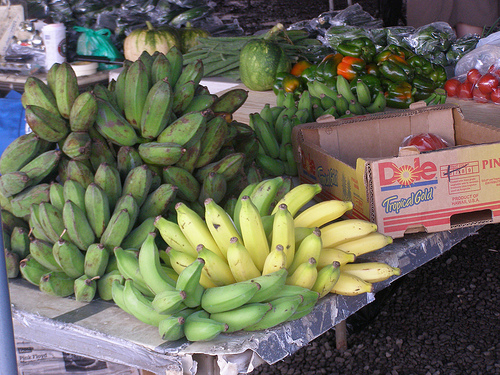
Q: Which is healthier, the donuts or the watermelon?
A: The watermelon is healthier than the donuts.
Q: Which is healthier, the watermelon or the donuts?
A: The watermelon is healthier than the donuts.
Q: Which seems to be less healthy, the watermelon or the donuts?
A: The donuts is less healthy than the watermelon.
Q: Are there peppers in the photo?
A: Yes, there are peppers.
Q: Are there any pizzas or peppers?
A: Yes, there are peppers.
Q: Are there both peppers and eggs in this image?
A: No, there are peppers but no eggs.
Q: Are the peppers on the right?
A: Yes, the peppers are on the right of the image.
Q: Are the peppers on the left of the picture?
A: No, the peppers are on the right of the image.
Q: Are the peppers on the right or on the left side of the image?
A: The peppers are on the right of the image.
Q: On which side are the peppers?
A: The peppers are on the right of the image.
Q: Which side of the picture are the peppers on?
A: The peppers are on the right of the image.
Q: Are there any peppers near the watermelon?
A: Yes, there are peppers near the watermelon.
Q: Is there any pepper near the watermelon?
A: Yes, there are peppers near the watermelon.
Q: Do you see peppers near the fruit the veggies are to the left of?
A: Yes, there are peppers near the watermelon.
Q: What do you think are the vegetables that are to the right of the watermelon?
A: The vegetables are peppers.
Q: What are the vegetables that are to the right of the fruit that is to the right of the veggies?
A: The vegetables are peppers.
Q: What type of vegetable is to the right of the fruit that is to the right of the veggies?
A: The vegetables are peppers.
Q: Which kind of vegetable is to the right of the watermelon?
A: The vegetables are peppers.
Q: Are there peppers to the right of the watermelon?
A: Yes, there are peppers to the right of the watermelon.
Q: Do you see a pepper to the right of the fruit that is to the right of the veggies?
A: Yes, there are peppers to the right of the watermelon.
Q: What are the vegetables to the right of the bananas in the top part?
A: The vegetables are peppers.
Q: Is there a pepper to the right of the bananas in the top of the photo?
A: Yes, there are peppers to the right of the bananas.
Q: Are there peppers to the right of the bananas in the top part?
A: Yes, there are peppers to the right of the bananas.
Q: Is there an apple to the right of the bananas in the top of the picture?
A: No, there are peppers to the right of the bananas.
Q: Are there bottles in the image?
A: No, there are no bottles.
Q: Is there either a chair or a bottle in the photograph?
A: No, there are no bottles or chairs.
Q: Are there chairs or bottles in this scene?
A: No, there are no bottles or chairs.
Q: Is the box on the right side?
A: Yes, the box is on the right of the image.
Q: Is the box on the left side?
A: No, the box is on the right of the image.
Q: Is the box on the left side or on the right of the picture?
A: The box is on the right of the image.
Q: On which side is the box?
A: The box is on the right of the image.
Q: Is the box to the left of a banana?
A: No, the box is to the right of a banana.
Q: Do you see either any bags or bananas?
A: Yes, there are bananas.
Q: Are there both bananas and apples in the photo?
A: No, there are bananas but no apples.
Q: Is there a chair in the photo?
A: No, there are no chairs.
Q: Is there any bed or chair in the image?
A: No, there are no chairs or beds.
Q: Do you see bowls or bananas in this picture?
A: Yes, there are bananas.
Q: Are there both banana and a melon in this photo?
A: No, there are bananas but no melons.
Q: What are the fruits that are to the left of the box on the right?
A: The fruits are bananas.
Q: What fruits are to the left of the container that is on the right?
A: The fruits are bananas.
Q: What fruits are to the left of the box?
A: The fruits are bananas.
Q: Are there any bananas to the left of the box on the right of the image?
A: Yes, there are bananas to the left of the box.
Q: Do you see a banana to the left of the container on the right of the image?
A: Yes, there are bananas to the left of the box.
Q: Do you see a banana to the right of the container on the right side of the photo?
A: No, the bananas are to the left of the box.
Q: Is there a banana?
A: Yes, there are bananas.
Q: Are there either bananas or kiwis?
A: Yes, there are bananas.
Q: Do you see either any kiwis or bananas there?
A: Yes, there are bananas.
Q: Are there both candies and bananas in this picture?
A: No, there are bananas but no candies.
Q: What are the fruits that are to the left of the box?
A: The fruits are bananas.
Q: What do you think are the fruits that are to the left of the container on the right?
A: The fruits are bananas.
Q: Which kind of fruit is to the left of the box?
A: The fruits are bananas.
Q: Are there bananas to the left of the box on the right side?
A: Yes, there are bananas to the left of the box.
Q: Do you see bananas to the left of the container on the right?
A: Yes, there are bananas to the left of the box.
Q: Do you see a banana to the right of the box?
A: No, the bananas are to the left of the box.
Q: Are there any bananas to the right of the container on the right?
A: No, the bananas are to the left of the box.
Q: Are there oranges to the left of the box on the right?
A: No, there are bananas to the left of the box.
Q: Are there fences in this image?
A: No, there are no fences.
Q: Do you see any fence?
A: No, there are no fences.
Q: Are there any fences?
A: No, there are no fences.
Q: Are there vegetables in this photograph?
A: Yes, there are vegetables.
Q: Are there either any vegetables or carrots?
A: Yes, there are vegetables.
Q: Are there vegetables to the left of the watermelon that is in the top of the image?
A: Yes, there are vegetables to the left of the watermelon.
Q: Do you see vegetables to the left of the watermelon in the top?
A: Yes, there are vegetables to the left of the watermelon.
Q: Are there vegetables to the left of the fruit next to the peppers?
A: Yes, there are vegetables to the left of the watermelon.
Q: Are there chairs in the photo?
A: No, there are no chairs.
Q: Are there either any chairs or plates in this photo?
A: No, there are no chairs or plates.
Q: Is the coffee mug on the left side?
A: Yes, the coffee mug is on the left of the image.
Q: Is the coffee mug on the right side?
A: No, the coffee mug is on the left of the image.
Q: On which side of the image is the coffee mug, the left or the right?
A: The coffee mug is on the left of the image.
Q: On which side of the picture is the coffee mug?
A: The coffee mug is on the left of the image.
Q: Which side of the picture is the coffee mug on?
A: The coffee mug is on the left of the image.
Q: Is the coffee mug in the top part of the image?
A: Yes, the coffee mug is in the top of the image.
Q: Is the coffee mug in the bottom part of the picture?
A: No, the coffee mug is in the top of the image.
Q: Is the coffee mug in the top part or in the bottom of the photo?
A: The coffee mug is in the top of the image.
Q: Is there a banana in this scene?
A: Yes, there are bananas.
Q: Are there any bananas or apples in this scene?
A: Yes, there are bananas.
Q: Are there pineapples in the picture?
A: No, there are no pineapples.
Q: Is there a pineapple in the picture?
A: No, there are no pineapples.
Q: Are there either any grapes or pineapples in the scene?
A: No, there are no pineapples or grapes.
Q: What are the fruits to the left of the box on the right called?
A: The fruits are bananas.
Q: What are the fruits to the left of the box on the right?
A: The fruits are bananas.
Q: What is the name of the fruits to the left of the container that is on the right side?
A: The fruits are bananas.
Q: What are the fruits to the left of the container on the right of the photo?
A: The fruits are bananas.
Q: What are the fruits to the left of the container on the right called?
A: The fruits are bananas.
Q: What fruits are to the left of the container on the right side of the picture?
A: The fruits are bananas.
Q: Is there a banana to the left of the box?
A: Yes, there are bananas to the left of the box.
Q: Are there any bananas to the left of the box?
A: Yes, there are bananas to the left of the box.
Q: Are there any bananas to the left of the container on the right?
A: Yes, there are bananas to the left of the box.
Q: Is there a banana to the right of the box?
A: No, the bananas are to the left of the box.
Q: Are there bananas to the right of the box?
A: No, the bananas are to the left of the box.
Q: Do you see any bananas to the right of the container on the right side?
A: No, the bananas are to the left of the box.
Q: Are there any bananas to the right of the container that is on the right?
A: No, the bananas are to the left of the box.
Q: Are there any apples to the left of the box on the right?
A: No, there are bananas to the left of the box.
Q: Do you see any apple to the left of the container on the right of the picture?
A: No, there are bananas to the left of the box.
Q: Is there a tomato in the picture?
A: Yes, there is a tomato.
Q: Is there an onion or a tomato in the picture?
A: Yes, there is a tomato.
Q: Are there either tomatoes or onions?
A: Yes, there is a tomato.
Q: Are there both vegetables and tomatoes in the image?
A: Yes, there are both a tomato and vegetables.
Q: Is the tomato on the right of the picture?
A: Yes, the tomato is on the right of the image.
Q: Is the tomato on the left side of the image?
A: No, the tomato is on the right of the image.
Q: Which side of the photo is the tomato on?
A: The tomato is on the right of the image.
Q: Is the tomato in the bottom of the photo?
A: No, the tomato is in the top of the image.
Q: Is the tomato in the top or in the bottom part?
A: The tomato is in the top of the image.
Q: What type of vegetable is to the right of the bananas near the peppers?
A: The vegetable is a tomato.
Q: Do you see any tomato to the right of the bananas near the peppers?
A: Yes, there is a tomato to the right of the bananas.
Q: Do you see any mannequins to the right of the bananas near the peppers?
A: No, there is a tomato to the right of the bananas.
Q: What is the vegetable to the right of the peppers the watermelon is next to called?
A: The vegetable is a tomato.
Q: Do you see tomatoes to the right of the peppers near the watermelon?
A: Yes, there is a tomato to the right of the peppers.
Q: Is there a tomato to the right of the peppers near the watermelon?
A: Yes, there is a tomato to the right of the peppers.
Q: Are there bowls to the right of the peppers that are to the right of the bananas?
A: No, there is a tomato to the right of the peppers.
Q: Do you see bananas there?
A: Yes, there are bananas.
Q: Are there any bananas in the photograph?
A: Yes, there are bananas.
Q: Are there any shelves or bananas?
A: Yes, there are bananas.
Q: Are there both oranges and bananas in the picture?
A: No, there are bananas but no oranges.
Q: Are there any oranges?
A: No, there are no oranges.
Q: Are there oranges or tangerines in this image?
A: No, there are no oranges or tangerines.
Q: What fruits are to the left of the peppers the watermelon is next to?
A: The fruits are bananas.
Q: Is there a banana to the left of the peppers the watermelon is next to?
A: Yes, there are bananas to the left of the peppers.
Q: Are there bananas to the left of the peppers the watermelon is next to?
A: Yes, there are bananas to the left of the peppers.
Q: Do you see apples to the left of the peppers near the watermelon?
A: No, there are bananas to the left of the peppers.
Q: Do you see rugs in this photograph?
A: No, there are no rugs.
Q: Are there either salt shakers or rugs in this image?
A: No, there are no rugs or salt shakers.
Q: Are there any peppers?
A: Yes, there are peppers.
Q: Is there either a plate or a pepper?
A: Yes, there are peppers.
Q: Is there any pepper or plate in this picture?
A: Yes, there are peppers.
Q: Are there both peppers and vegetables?
A: Yes, there are both peppers and vegetables.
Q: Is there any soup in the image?
A: No, there is no soup.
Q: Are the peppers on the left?
A: No, the peppers are on the right of the image.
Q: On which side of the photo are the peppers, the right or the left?
A: The peppers are on the right of the image.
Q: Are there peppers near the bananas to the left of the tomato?
A: Yes, there are peppers near the bananas.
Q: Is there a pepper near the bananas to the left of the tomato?
A: Yes, there are peppers near the bananas.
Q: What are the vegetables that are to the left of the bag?
A: The vegetables are peppers.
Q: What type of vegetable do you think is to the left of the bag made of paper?
A: The vegetables are peppers.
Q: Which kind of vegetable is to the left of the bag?
A: The vegetables are peppers.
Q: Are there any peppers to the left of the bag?
A: Yes, there are peppers to the left of the bag.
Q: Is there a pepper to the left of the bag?
A: Yes, there are peppers to the left of the bag.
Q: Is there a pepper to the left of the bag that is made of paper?
A: Yes, there are peppers to the left of the bag.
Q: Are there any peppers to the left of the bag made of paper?
A: Yes, there are peppers to the left of the bag.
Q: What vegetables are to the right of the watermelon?
A: The vegetables are peppers.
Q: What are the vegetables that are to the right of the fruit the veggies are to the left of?
A: The vegetables are peppers.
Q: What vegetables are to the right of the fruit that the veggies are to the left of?
A: The vegetables are peppers.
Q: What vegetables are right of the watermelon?
A: The vegetables are peppers.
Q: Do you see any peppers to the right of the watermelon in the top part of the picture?
A: Yes, there are peppers to the right of the watermelon.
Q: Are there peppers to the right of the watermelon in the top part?
A: Yes, there are peppers to the right of the watermelon.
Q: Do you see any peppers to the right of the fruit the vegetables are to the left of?
A: Yes, there are peppers to the right of the watermelon.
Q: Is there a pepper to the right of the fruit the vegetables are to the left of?
A: Yes, there are peppers to the right of the watermelon.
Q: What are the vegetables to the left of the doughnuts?
A: The vegetables are peppers.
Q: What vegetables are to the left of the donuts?
A: The vegetables are peppers.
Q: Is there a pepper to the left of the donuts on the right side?
A: Yes, there are peppers to the left of the doughnuts.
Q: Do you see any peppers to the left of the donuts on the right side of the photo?
A: Yes, there are peppers to the left of the doughnuts.